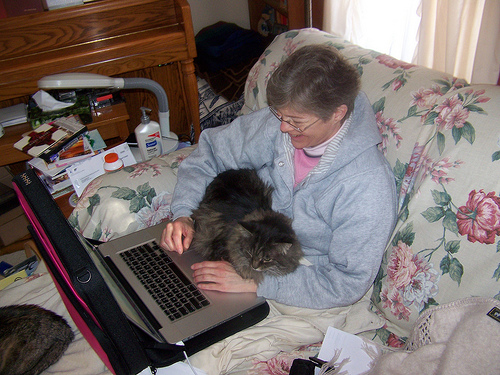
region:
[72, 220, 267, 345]
silver and black laptop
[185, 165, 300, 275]
dark gray fluffy long haired cat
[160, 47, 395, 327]
older woman sitting on sofa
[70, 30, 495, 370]
flower print sofa in front of window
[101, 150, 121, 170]
red and white pill bottle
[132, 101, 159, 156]
bottle of skin lotion next to sofa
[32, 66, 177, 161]
gray table lamp near sofa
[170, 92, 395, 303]
gray hooded shirt on lady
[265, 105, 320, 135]
glasses on womans face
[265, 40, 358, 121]
short gray hair on woman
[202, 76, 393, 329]
One woman and cat is seen.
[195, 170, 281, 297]
Cat is grey color.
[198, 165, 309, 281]
Cat is sitting in the woman lap.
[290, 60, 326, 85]
Hair is grey color.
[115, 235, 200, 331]
Laptop is grey and black color.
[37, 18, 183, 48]
cupboard is brown color.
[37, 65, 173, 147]
One lamp is seen.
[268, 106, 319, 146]
Lady is wearing eyeglass.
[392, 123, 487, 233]
Sofa cover has floral prints.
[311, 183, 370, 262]
Woman wears grey coat.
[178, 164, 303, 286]
beautiful gray long hair adult cat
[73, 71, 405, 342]
elderly lady working on a lap top computer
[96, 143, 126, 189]
one large bottle of tylenol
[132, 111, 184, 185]
one large bottle of Suave lotion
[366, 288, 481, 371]
cream color throw with lace on edge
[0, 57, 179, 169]
feel better happy light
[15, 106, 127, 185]
assorted mail and envelopes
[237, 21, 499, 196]
large floral sofa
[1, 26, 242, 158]
large wooden piano with bench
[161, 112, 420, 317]
unisex blue hoodie jacket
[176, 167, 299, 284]
a cat in a lap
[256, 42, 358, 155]
a woman with a smile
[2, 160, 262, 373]
a large laptop in use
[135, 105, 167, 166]
a bottle with a pump dispenser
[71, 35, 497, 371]
a sofa with a flower pattern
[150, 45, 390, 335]
woman with a blue hoodie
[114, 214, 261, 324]
hands near a keyboard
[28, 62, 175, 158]
a directional lamp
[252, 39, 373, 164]
a rare woman who does not color her hair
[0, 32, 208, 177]
an upright or spinet piano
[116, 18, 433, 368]
woman sitting on couch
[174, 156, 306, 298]
cat sitting on woman's lap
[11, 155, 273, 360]
laptop in pink and black case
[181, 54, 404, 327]
woman wearing grey hoodie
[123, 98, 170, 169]
jar of lotion on table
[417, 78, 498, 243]
flowers on couch cover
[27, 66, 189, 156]
lamp on side table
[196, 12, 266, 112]
duffle bag behind cabinet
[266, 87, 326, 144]
silver, wire framed eyeglasses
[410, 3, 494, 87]
white curtains over windows